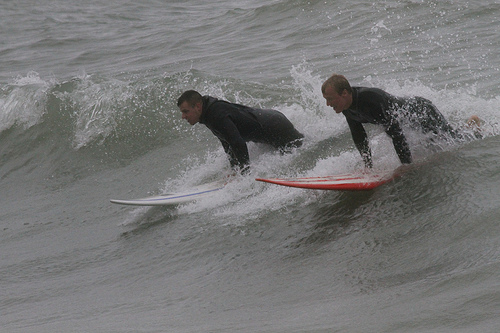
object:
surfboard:
[255, 172, 396, 190]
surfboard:
[110, 173, 239, 206]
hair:
[321, 73, 352, 96]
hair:
[176, 90, 203, 108]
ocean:
[0, 0, 500, 333]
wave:
[2, 63, 499, 265]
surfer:
[321, 73, 484, 175]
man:
[176, 89, 304, 177]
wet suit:
[200, 92, 304, 176]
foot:
[467, 114, 484, 139]